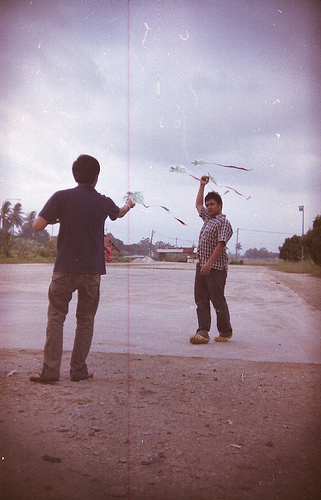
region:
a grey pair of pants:
[43, 272, 100, 382]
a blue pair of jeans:
[194, 264, 235, 335]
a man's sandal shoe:
[28, 370, 55, 381]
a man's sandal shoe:
[71, 369, 95, 379]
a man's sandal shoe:
[188, 334, 210, 342]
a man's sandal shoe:
[214, 333, 230, 340]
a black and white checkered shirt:
[197, 206, 232, 269]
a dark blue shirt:
[39, 185, 119, 274]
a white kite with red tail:
[120, 188, 190, 228]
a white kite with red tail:
[168, 162, 204, 184]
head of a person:
[66, 149, 108, 182]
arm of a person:
[22, 195, 65, 243]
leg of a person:
[27, 268, 78, 349]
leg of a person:
[54, 287, 113, 364]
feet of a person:
[22, 366, 70, 389]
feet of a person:
[60, 360, 113, 393]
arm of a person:
[104, 201, 139, 229]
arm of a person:
[189, 184, 214, 214]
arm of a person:
[205, 236, 227, 265]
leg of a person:
[179, 273, 214, 329]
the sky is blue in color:
[131, 87, 189, 115]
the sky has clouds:
[207, 62, 310, 146]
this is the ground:
[139, 387, 216, 423]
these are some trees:
[2, 200, 29, 260]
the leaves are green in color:
[9, 255, 19, 261]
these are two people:
[28, 151, 247, 407]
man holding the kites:
[165, 138, 257, 359]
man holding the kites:
[149, 131, 268, 362]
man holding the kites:
[168, 150, 240, 345]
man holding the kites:
[163, 145, 263, 384]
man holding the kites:
[163, 139, 259, 354]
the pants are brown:
[32, 267, 107, 392]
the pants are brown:
[25, 265, 117, 397]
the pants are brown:
[37, 266, 120, 407]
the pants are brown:
[31, 268, 117, 391]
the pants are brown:
[23, 269, 112, 401]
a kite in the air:
[190, 144, 226, 176]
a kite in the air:
[113, 166, 162, 228]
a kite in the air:
[173, 218, 190, 234]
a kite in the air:
[139, 73, 180, 98]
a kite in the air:
[178, 25, 191, 48]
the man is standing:
[31, 154, 134, 381]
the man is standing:
[189, 174, 233, 342]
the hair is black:
[71, 153, 99, 185]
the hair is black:
[203, 190, 223, 206]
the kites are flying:
[124, 159, 252, 227]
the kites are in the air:
[124, 159, 252, 228]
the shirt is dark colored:
[37, 184, 120, 276]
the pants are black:
[193, 261, 231, 336]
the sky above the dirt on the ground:
[0, 0, 320, 499]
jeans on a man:
[43, 267, 97, 372]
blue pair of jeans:
[190, 255, 234, 331]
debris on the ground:
[32, 449, 62, 465]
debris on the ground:
[139, 448, 170, 469]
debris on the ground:
[229, 437, 244, 451]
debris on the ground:
[223, 416, 236, 428]